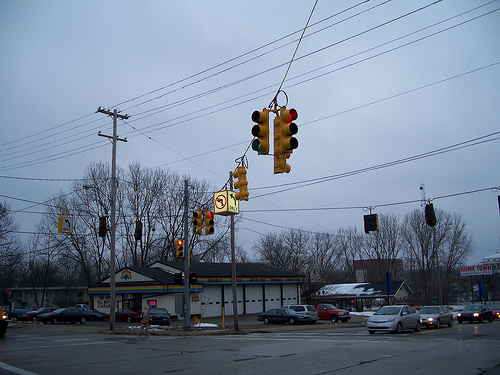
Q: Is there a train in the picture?
A: No, there are no trains.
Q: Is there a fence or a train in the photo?
A: No, there are no trains or fences.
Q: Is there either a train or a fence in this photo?
A: No, there are no trains or fences.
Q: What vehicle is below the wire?
A: The vehicle is a car.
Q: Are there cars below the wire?
A: Yes, there is a car below the wire.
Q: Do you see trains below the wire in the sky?
A: No, there is a car below the wire.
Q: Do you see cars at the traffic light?
A: Yes, there is a car at the traffic light.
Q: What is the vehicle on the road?
A: The vehicle is a car.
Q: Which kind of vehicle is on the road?
A: The vehicle is a car.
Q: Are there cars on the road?
A: Yes, there is a car on the road.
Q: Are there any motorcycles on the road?
A: No, there is a car on the road.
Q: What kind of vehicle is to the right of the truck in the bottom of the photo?
A: The vehicle is a car.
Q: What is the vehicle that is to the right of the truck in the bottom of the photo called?
A: The vehicle is a car.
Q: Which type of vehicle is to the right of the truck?
A: The vehicle is a car.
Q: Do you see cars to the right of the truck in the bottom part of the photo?
A: Yes, there is a car to the right of the truck.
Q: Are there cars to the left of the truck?
A: No, the car is to the right of the truck.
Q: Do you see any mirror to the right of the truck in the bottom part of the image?
A: No, there is a car to the right of the truck.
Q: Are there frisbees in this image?
A: No, there are no frisbees.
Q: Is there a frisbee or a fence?
A: No, there are no frisbees or fences.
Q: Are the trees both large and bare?
A: Yes, the trees are large and bare.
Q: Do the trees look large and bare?
A: Yes, the trees are large and bare.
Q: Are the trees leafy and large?
A: No, the trees are large but bare.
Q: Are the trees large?
A: Yes, the trees are large.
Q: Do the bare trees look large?
A: Yes, the trees are large.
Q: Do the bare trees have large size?
A: Yes, the trees are large.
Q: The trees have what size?
A: The trees are large.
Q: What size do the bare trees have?
A: The trees have large size.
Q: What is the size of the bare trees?
A: The trees are large.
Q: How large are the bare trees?
A: The trees are large.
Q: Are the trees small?
A: No, the trees are large.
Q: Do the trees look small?
A: No, the trees are large.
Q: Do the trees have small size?
A: No, the trees are large.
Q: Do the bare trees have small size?
A: No, the trees are large.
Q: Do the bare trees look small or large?
A: The trees are large.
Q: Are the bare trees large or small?
A: The trees are large.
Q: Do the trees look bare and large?
A: Yes, the trees are bare and large.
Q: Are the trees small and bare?
A: No, the trees are bare but large.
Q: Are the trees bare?
A: Yes, the trees are bare.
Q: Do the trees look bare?
A: Yes, the trees are bare.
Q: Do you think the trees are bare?
A: Yes, the trees are bare.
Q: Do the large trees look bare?
A: Yes, the trees are bare.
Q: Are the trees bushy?
A: No, the trees are bare.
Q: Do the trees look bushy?
A: No, the trees are bare.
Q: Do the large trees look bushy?
A: No, the trees are bare.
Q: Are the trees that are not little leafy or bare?
A: The trees are bare.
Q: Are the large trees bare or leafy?
A: The trees are bare.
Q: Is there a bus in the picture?
A: No, there are no buses.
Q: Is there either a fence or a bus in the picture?
A: No, there are no buses or fences.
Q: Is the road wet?
A: Yes, the road is wet.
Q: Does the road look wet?
A: Yes, the road is wet.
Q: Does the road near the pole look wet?
A: Yes, the road is wet.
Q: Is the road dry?
A: No, the road is wet.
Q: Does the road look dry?
A: No, the road is wet.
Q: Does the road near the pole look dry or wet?
A: The road is wet.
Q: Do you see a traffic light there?
A: Yes, there is a traffic light.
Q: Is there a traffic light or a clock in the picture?
A: Yes, there is a traffic light.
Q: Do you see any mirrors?
A: No, there are no mirrors.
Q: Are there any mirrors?
A: No, there are no mirrors.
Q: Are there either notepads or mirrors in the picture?
A: No, there are no mirrors or notepads.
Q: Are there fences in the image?
A: No, there are no fences.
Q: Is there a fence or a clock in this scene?
A: No, there are no fences or clocks.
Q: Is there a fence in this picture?
A: No, there are no fences.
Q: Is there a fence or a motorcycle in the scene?
A: No, there are no fences or motorcycles.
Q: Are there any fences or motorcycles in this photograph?
A: No, there are no fences or motorcycles.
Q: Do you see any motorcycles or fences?
A: No, there are no fences or motorcycles.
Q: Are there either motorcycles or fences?
A: No, there are no fences or motorcycles.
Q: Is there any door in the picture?
A: Yes, there is a door.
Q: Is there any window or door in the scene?
A: Yes, there is a door.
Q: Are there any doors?
A: Yes, there is a door.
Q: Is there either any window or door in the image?
A: Yes, there is a door.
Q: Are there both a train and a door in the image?
A: No, there is a door but no trains.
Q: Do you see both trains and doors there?
A: No, there is a door but no trains.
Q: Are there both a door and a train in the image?
A: No, there is a door but no trains.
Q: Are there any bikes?
A: No, there are no bikes.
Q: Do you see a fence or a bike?
A: No, there are no bikes or fences.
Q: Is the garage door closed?
A: Yes, the garage door is closed.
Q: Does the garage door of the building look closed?
A: Yes, the garage door is closed.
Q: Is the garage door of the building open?
A: No, the garage door is closed.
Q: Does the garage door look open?
A: No, the garage door is closed.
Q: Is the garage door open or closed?
A: The garage door is closed.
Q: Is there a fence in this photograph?
A: No, there are no fences.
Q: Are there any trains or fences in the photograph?
A: No, there are no fences or trains.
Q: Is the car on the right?
A: Yes, the car is on the right of the image.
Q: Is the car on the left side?
A: No, the car is on the right of the image.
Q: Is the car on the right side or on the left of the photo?
A: The car is on the right of the image.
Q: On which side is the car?
A: The car is on the right of the image.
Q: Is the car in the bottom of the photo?
A: Yes, the car is in the bottom of the image.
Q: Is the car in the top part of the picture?
A: No, the car is in the bottom of the image.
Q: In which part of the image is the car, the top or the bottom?
A: The car is in the bottom of the image.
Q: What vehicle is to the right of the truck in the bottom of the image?
A: The vehicle is a car.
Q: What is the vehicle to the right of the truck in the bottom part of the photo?
A: The vehicle is a car.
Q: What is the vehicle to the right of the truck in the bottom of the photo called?
A: The vehicle is a car.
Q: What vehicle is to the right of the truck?
A: The vehicle is a car.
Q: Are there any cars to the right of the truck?
A: Yes, there is a car to the right of the truck.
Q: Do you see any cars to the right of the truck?
A: Yes, there is a car to the right of the truck.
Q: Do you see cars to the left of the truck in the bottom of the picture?
A: No, the car is to the right of the truck.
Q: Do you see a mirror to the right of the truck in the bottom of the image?
A: No, there is a car to the right of the truck.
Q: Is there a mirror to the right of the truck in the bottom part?
A: No, there is a car to the right of the truck.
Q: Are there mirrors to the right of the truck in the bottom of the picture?
A: No, there is a car to the right of the truck.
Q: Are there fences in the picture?
A: No, there are no fences.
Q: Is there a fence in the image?
A: No, there are no fences.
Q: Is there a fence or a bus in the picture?
A: No, there are no fences or buses.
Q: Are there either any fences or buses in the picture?
A: No, there are no fences or buses.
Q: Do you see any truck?
A: Yes, there is a truck.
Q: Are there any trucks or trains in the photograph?
A: Yes, there is a truck.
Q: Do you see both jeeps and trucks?
A: No, there is a truck but no jeeps.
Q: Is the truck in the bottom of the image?
A: Yes, the truck is in the bottom of the image.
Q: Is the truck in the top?
A: No, the truck is in the bottom of the image.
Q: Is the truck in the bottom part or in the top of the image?
A: The truck is in the bottom of the image.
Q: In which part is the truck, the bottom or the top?
A: The truck is in the bottom of the image.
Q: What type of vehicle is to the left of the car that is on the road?
A: The vehicle is a truck.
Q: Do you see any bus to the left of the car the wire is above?
A: No, there is a truck to the left of the car.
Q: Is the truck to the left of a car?
A: Yes, the truck is to the left of a car.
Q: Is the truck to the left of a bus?
A: No, the truck is to the left of a car.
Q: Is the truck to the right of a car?
A: No, the truck is to the left of a car.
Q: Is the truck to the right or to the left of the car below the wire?
A: The truck is to the left of the car.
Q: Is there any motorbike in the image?
A: No, there are no motorcycles.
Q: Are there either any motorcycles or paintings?
A: No, there are no motorcycles or paintings.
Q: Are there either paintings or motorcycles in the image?
A: No, there are no motorcycles or paintings.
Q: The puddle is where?
A: The puddle is on the road.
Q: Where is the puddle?
A: The puddle is on the road.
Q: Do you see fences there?
A: No, there are no fences.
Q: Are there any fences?
A: No, there are no fences.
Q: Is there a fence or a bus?
A: No, there are no fences or buses.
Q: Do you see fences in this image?
A: No, there are no fences.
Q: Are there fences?
A: No, there are no fences.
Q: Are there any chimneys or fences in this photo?
A: No, there are no fences or chimneys.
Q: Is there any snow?
A: Yes, there is snow.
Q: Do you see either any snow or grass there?
A: Yes, there is snow.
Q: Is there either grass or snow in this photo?
A: Yes, there is snow.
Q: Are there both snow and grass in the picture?
A: No, there is snow but no grass.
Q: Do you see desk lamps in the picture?
A: No, there are no desk lamps.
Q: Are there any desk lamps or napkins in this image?
A: No, there are no desk lamps or napkins.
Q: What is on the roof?
A: The snow is on the roof.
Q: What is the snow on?
A: The snow is on the roof.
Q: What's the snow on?
A: The snow is on the roof.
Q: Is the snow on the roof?
A: Yes, the snow is on the roof.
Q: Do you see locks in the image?
A: No, there are no locks.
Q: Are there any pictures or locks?
A: No, there are no locks or pictures.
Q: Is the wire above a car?
A: Yes, the wire is above a car.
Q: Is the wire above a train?
A: No, the wire is above a car.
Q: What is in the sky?
A: The wire is in the sky.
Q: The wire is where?
A: The wire is in the sky.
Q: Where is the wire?
A: The wire is in the sky.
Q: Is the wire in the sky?
A: Yes, the wire is in the sky.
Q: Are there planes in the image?
A: No, there are no planes.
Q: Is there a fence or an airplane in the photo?
A: No, there are no airplanes or fences.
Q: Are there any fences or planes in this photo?
A: No, there are no planes or fences.